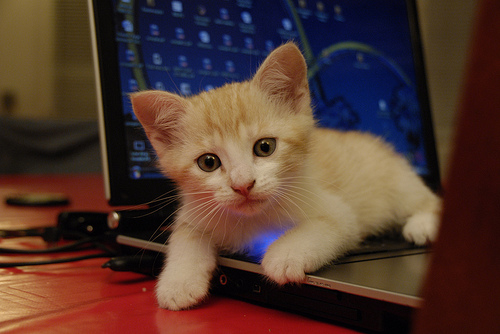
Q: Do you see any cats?
A: Yes, there is a cat.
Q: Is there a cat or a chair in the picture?
A: Yes, there is a cat.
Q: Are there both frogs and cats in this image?
A: No, there is a cat but no frogs.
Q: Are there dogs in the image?
A: No, there are no dogs.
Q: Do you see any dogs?
A: No, there are no dogs.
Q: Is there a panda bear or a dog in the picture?
A: No, there are no dogs or panda bears.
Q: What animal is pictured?
A: The animal is a cat.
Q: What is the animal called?
A: The animal is a cat.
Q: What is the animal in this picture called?
A: The animal is a cat.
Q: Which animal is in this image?
A: The animal is a cat.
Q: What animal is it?
A: The animal is a cat.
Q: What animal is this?
A: This is a cat.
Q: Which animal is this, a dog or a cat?
A: This is a cat.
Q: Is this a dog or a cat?
A: This is a cat.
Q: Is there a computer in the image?
A: Yes, there is a computer.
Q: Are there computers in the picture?
A: Yes, there is a computer.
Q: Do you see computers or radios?
A: Yes, there is a computer.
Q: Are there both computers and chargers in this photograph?
A: No, there is a computer but no chargers.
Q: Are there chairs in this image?
A: No, there are no chairs.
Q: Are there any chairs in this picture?
A: No, there are no chairs.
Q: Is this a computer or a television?
A: This is a computer.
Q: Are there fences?
A: No, there are no fences.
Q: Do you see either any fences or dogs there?
A: No, there are no fences or dogs.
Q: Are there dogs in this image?
A: No, there are no dogs.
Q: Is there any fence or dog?
A: No, there are no dogs or fences.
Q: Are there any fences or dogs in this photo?
A: No, there are no dogs or fences.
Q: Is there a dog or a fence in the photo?
A: No, there are no dogs or fences.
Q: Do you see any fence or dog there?
A: No, there are no dogs or fences.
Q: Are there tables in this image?
A: Yes, there is a table.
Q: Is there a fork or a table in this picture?
A: Yes, there is a table.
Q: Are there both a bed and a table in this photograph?
A: No, there is a table but no beds.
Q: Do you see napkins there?
A: No, there are no napkins.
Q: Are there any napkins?
A: No, there are no napkins.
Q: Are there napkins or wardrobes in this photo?
A: No, there are no napkins or wardrobes.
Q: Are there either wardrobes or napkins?
A: No, there are no napkins or wardrobes.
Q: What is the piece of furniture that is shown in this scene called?
A: The piece of furniture is a table.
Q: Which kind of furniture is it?
A: The piece of furniture is a table.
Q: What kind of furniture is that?
A: That is a table.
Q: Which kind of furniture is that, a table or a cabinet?
A: That is a table.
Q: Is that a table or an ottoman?
A: That is a table.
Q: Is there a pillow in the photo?
A: No, there are no pillows.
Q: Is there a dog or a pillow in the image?
A: No, there are no pillows or dogs.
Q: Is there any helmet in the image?
A: No, there are no helmets.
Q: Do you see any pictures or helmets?
A: No, there are no helmets or pictures.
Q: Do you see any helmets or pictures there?
A: No, there are no helmets or pictures.